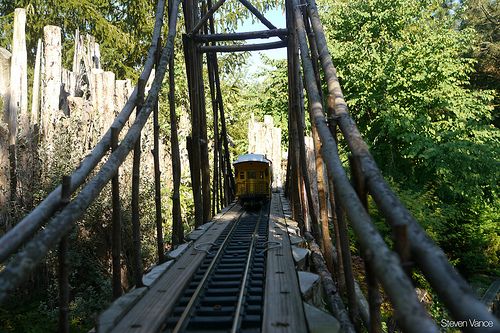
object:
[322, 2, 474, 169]
trees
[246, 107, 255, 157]
woods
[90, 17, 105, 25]
leaves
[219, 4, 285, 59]
sky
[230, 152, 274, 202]
train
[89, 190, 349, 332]
bridge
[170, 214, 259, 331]
tracks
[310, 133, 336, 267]
trunks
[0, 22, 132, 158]
wall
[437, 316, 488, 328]
watermark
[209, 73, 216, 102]
ropes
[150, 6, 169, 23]
rod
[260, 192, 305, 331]
plank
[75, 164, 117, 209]
logs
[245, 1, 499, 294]
forest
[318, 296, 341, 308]
water